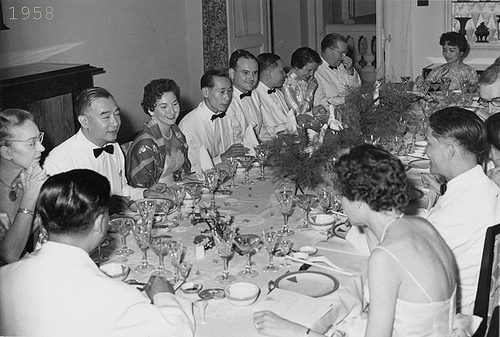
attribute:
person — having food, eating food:
[39, 86, 147, 208]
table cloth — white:
[98, 82, 468, 336]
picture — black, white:
[1, 1, 499, 336]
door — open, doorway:
[321, 1, 393, 87]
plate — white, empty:
[272, 271, 341, 301]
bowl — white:
[308, 211, 336, 232]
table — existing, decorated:
[39, 80, 499, 316]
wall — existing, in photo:
[0, 1, 202, 137]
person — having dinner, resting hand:
[326, 141, 481, 337]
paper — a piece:
[244, 282, 337, 332]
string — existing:
[370, 242, 433, 307]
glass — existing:
[230, 233, 264, 280]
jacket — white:
[229, 86, 266, 143]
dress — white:
[365, 243, 484, 337]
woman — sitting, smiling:
[422, 31, 486, 93]